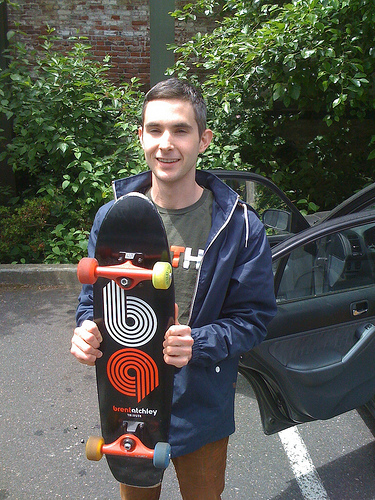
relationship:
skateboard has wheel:
[47, 192, 202, 464] [70, 254, 106, 288]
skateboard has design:
[47, 192, 202, 464] [88, 286, 150, 401]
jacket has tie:
[176, 225, 289, 460] [217, 199, 260, 247]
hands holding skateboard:
[163, 324, 201, 368] [47, 192, 202, 464]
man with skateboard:
[85, 69, 291, 473] [47, 192, 202, 464]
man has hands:
[85, 69, 291, 473] [163, 324, 201, 368]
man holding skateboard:
[85, 69, 291, 473] [47, 192, 202, 464]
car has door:
[251, 149, 369, 358] [310, 238, 373, 379]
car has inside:
[251, 149, 369, 358] [334, 222, 371, 267]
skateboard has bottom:
[47, 192, 202, 464] [96, 350, 176, 423]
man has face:
[85, 69, 291, 473] [148, 102, 197, 173]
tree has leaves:
[30, 57, 106, 160] [59, 112, 78, 133]